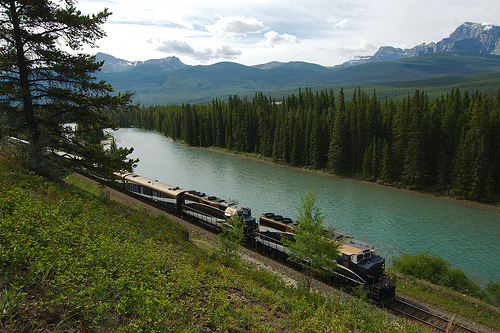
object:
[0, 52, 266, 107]
mountain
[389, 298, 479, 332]
track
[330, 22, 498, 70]
mountains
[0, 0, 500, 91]
horizon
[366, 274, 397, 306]
handrail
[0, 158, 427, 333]
grassy land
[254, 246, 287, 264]
tracks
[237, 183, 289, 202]
reflection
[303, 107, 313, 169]
pine tree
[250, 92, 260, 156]
pine tree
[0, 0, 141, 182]
tree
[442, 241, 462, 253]
water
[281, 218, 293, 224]
black holes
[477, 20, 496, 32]
snow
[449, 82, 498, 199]
trees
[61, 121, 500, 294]
river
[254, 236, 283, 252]
white mark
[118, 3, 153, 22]
sky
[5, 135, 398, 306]
train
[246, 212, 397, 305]
car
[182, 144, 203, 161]
water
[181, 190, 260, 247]
cars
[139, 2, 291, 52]
clouds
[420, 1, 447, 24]
sky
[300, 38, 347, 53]
sky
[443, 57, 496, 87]
land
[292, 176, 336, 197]
ripples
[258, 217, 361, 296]
side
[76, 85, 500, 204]
forest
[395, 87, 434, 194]
tree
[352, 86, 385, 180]
tree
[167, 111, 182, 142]
tree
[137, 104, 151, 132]
tree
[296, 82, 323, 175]
tree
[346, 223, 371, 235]
water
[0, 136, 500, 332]
hill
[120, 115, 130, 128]
evergreen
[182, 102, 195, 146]
evergreen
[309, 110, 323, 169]
evergreen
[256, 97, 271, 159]
evergreen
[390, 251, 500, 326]
brush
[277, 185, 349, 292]
tree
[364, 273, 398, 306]
steps